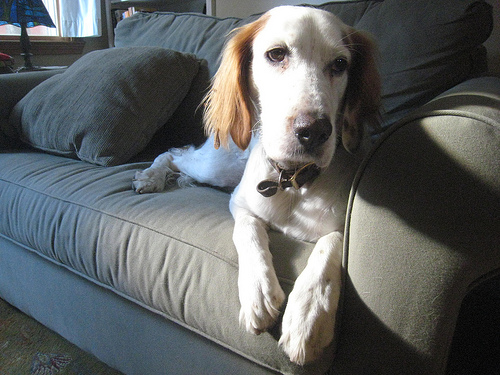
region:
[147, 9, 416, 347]
a dog staring past the camera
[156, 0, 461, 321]
a melancholy looking dog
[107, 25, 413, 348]
a dog deep in thought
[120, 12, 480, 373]
a dog with its paws out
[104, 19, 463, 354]
a dog sitting in the sun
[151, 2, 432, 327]
a dog lying on a couch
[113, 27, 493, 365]
dog lying down on a couch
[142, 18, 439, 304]
a white dog with floppy ears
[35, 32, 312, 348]
a pillow on the couch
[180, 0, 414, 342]
a sad looking dog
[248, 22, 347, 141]
White-faced dog with brown eyes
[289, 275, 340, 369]
A dogs paw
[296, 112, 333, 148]
A dog's brown nose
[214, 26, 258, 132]
A dog's light brown ear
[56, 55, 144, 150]
A grey sofa pillow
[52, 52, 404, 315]
A grey sofa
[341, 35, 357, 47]
White whispers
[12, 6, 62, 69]
A lamp with a blue cover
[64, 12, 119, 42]
Window's white curtain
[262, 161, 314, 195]
A collar around the neck of a dog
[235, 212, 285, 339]
the leg of a dog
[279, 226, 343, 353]
the leg of a dog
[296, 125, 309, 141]
the nostril of a dog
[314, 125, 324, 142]
the nostril of a dog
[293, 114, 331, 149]
the nose of a dog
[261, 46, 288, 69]
the eye of a dog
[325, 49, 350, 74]
the eye of a dog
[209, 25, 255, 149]
the ear of a dog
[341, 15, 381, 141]
the ear of a dog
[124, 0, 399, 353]
a cute dog on a chair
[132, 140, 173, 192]
the leg of a dog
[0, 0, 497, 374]
dimly lit living room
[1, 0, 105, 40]
window in living room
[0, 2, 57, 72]
lamp in front of window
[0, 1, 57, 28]
blue Tiffany style lampshade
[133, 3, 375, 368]
dog on beige couch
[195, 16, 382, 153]
dog has soft brown ears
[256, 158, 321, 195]
dog wears brown collar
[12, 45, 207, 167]
throw pillow on sofa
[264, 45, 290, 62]
dog's gentle brown eye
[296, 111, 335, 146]
dog's wet, black nose